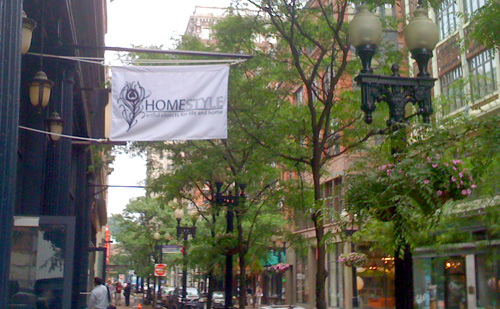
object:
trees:
[221, 0, 454, 309]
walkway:
[114, 207, 288, 309]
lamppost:
[357, 56, 436, 309]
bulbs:
[347, 5, 385, 48]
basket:
[336, 249, 369, 268]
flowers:
[348, 257, 356, 262]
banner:
[103, 63, 231, 142]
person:
[86, 276, 112, 309]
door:
[83, 273, 110, 309]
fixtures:
[23, 67, 54, 118]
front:
[0, 49, 105, 297]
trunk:
[305, 124, 332, 308]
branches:
[321, 129, 386, 165]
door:
[7, 215, 64, 309]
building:
[180, 5, 229, 54]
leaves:
[242, 110, 286, 173]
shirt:
[87, 286, 110, 309]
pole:
[356, 62, 438, 309]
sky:
[118, 6, 172, 34]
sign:
[152, 262, 169, 277]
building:
[0, 0, 107, 309]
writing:
[144, 95, 223, 116]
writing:
[156, 265, 168, 276]